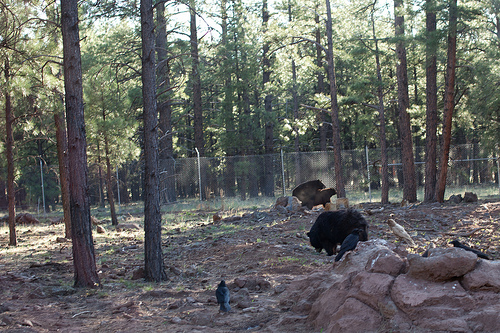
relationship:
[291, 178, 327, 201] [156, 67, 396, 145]
bear in background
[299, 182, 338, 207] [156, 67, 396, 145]
bear in background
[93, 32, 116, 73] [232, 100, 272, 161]
leaf on a plant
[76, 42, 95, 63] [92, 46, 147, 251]
leaf on a plant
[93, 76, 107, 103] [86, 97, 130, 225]
leaf on a plant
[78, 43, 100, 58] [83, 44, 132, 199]
leaf on a plant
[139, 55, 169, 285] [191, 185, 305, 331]
tree in a field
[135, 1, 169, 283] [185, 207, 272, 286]
tree in a field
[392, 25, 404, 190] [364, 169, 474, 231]
tree in a field